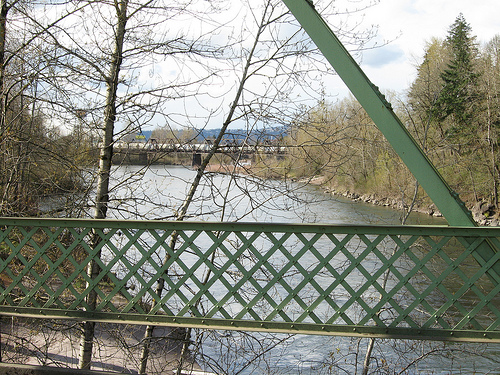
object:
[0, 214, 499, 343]
fence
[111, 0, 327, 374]
trees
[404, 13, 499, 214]
pine tree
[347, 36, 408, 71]
clouds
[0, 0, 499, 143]
sky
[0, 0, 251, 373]
trees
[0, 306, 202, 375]
river bank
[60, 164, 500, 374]
water